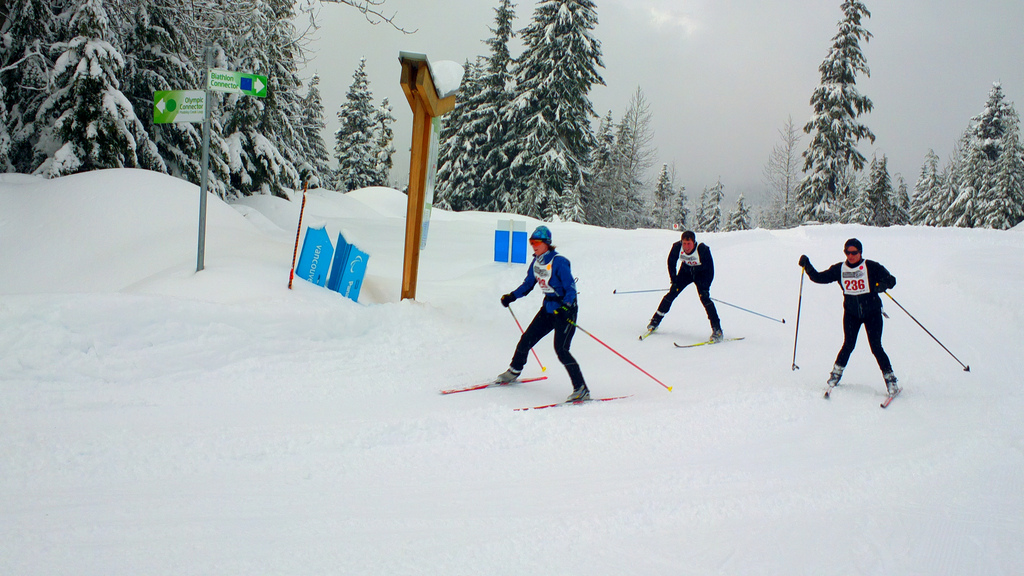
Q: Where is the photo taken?
A: On a ski slope.